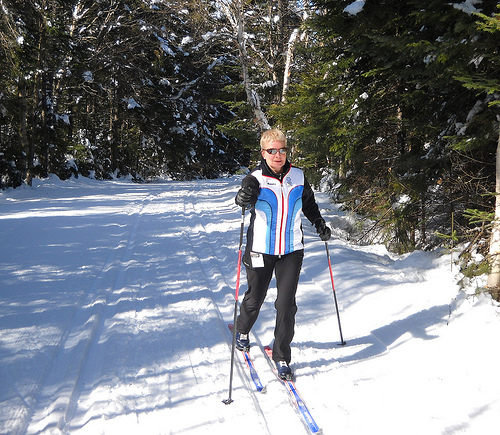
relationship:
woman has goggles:
[231, 124, 335, 382] [261, 146, 289, 156]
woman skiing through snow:
[231, 124, 335, 382] [1, 174, 499, 435]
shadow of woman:
[276, 285, 473, 383] [231, 124, 335, 382]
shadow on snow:
[276, 285, 473, 383] [1, 174, 499, 435]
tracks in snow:
[178, 185, 292, 430] [1, 174, 499, 435]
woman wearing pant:
[231, 124, 335, 382] [232, 244, 304, 365]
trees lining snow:
[1, 1, 499, 289] [1, 174, 499, 435]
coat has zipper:
[235, 160, 327, 262] [275, 185, 286, 261]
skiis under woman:
[226, 320, 323, 435] [231, 124, 335, 382]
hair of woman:
[254, 127, 288, 150] [231, 124, 335, 382]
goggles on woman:
[261, 146, 289, 156] [231, 124, 335, 382]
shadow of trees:
[1, 176, 412, 434] [1, 1, 499, 289]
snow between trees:
[1, 174, 499, 435] [1, 1, 499, 289]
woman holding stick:
[231, 124, 335, 382] [321, 232, 351, 345]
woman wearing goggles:
[231, 124, 335, 382] [261, 146, 289, 156]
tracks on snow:
[178, 185, 292, 430] [1, 174, 499, 435]